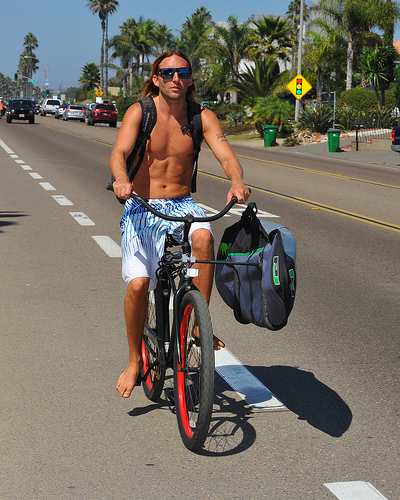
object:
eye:
[160, 67, 174, 80]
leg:
[170, 209, 215, 323]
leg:
[119, 208, 152, 356]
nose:
[170, 73, 181, 85]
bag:
[213, 204, 295, 331]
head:
[150, 50, 195, 99]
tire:
[164, 288, 219, 457]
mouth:
[169, 85, 180, 93]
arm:
[108, 101, 141, 179]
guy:
[107, 49, 249, 398]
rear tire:
[139, 280, 166, 400]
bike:
[105, 181, 251, 452]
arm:
[200, 111, 242, 183]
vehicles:
[2, 91, 116, 129]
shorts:
[119, 192, 214, 288]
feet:
[114, 364, 142, 398]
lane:
[4, 169, 347, 494]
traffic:
[0, 90, 42, 123]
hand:
[111, 175, 133, 197]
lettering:
[187, 191, 280, 220]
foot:
[191, 324, 226, 352]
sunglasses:
[155, 65, 191, 78]